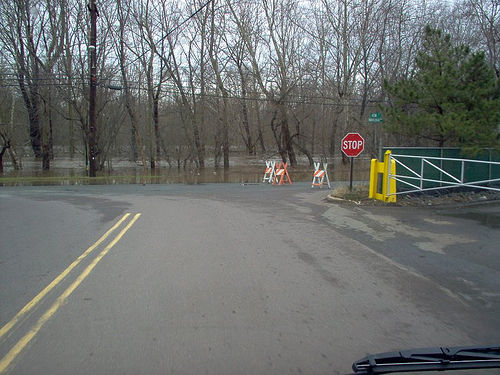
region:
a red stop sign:
[329, 125, 368, 200]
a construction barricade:
[260, 154, 299, 190]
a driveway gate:
[364, 140, 498, 233]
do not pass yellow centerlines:
[6, 193, 148, 373]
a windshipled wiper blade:
[330, 322, 488, 367]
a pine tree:
[382, 19, 487, 194]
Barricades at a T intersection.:
[248, 143, 341, 198]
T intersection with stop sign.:
[2, 115, 430, 220]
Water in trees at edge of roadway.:
[8, 128, 344, 169]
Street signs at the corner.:
[360, 111, 391, 128]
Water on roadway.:
[332, 197, 489, 321]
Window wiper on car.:
[345, 324, 497, 371]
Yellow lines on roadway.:
[1, 190, 158, 373]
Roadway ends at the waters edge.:
[4, 110, 471, 254]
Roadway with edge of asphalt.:
[141, 202, 494, 352]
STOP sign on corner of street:
[331, 121, 373, 211]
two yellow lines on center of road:
[8, 192, 168, 367]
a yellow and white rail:
[365, 149, 497, 211]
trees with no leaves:
[7, 6, 352, 164]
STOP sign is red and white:
[336, 129, 370, 195]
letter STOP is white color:
[338, 136, 364, 151]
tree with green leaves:
[379, 29, 499, 151]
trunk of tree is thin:
[138, 23, 170, 176]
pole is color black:
[76, 5, 116, 185]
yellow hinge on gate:
[359, 146, 404, 206]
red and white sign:
[338, 131, 365, 181]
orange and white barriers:
[234, 132, 334, 213]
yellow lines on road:
[68, 203, 181, 370]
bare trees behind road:
[113, 8, 330, 176]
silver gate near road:
[396, 157, 498, 217]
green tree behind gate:
[366, 15, 495, 163]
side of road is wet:
[359, 202, 494, 317]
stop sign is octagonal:
[326, 126, 366, 163]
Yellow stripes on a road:
[1, 211, 143, 371]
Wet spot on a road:
[7, 193, 132, 221]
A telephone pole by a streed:
[86, 0, 98, 176]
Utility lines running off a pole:
[1, 70, 394, 107]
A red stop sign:
[340, 131, 364, 189]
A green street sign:
[368, 110, 382, 124]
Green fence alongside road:
[378, 144, 498, 190]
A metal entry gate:
[385, 152, 499, 199]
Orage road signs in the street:
[260, 158, 333, 188]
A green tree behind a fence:
[386, 23, 499, 149]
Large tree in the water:
[23, 134, 58, 175]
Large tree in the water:
[124, 134, 159, 177]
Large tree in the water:
[158, 136, 182, 175]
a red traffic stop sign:
[340, 130, 364, 159]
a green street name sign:
[365, 116, 382, 123]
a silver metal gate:
[384, 152, 499, 211]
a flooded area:
[2, 154, 374, 186]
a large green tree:
[380, 27, 497, 149]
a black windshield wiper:
[350, 344, 498, 371]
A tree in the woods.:
[206, 0, 237, 190]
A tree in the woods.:
[172, 10, 222, 185]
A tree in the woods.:
[133, 11, 181, 176]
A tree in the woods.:
[92, 10, 126, 177]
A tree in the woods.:
[388, 20, 478, 179]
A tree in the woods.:
[298, 7, 371, 183]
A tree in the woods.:
[215, 19, 258, 167]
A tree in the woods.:
[159, 22, 208, 167]